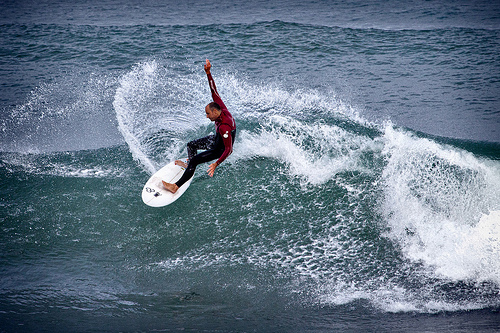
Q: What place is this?
A: It is an ocean.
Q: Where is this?
A: This is at the ocean.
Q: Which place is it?
A: It is an ocean.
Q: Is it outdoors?
A: Yes, it is outdoors.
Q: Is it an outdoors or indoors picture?
A: It is outdoors.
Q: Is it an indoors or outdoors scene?
A: It is outdoors.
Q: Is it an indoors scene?
A: No, it is outdoors.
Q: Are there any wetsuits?
A: Yes, there is a wetsuit.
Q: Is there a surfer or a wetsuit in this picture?
A: Yes, there is a wetsuit.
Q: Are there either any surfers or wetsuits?
A: Yes, there is a wetsuit.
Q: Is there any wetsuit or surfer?
A: Yes, there is a wetsuit.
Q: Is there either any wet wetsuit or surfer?
A: Yes, there is a wet wetsuit.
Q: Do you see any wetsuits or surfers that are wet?
A: Yes, the wetsuit is wet.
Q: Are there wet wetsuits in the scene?
A: Yes, there is a wet wetsuit.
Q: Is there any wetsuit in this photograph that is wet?
A: Yes, there is a wetsuit that is wet.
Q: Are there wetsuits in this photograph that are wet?
A: Yes, there is a wetsuit that is wet.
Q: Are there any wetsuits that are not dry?
A: Yes, there is a wet wetsuit.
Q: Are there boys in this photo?
A: No, there are no boys.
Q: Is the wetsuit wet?
A: Yes, the wetsuit is wet.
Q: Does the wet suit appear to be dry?
A: No, the wet suit is wet.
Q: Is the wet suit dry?
A: No, the wet suit is wet.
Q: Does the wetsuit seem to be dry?
A: No, the wetsuit is wet.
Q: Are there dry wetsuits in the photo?
A: No, there is a wetsuit but it is wet.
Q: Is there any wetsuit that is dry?
A: No, there is a wetsuit but it is wet.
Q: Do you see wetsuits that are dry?
A: No, there is a wetsuit but it is wet.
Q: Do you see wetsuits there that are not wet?
A: No, there is a wetsuit but it is wet.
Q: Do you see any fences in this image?
A: No, there are no fences.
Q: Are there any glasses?
A: No, there are no glasses.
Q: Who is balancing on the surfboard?
A: The man is balancing on the surfboard.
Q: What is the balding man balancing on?
A: The man is balancing on the surfboard.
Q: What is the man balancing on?
A: The man is balancing on the surfboard.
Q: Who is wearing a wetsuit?
A: The man is wearing a wetsuit.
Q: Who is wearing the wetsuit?
A: The man is wearing a wetsuit.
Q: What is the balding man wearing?
A: The man is wearing a wetsuit.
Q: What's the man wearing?
A: The man is wearing a wetsuit.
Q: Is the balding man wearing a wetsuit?
A: Yes, the man is wearing a wetsuit.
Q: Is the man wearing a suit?
A: No, the man is wearing a wetsuit.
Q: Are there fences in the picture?
A: No, there are no fences.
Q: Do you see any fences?
A: No, there are no fences.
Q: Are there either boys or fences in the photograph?
A: No, there are no fences or boys.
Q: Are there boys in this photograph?
A: No, there are no boys.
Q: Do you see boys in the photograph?
A: No, there are no boys.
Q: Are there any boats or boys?
A: No, there are no boys or boats.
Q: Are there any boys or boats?
A: No, there are no boys or boats.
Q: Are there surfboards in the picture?
A: Yes, there is a surfboard.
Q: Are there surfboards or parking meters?
A: Yes, there is a surfboard.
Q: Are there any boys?
A: No, there are no boys.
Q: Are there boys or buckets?
A: No, there are no boys or buckets.